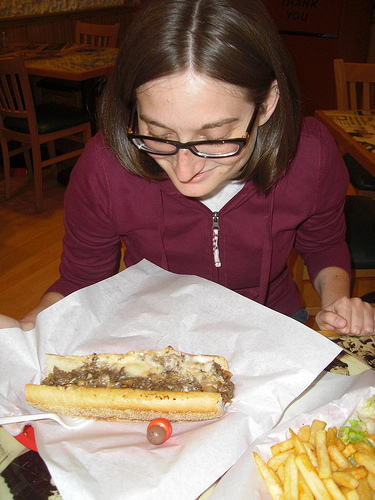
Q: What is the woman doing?
A: Looking at the food.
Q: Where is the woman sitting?
A: At a table.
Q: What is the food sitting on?
A: White paper.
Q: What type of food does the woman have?
A: A sandwich.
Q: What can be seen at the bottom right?
A: French fries.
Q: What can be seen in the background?
A: Table and chairs.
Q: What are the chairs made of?
A: Wood.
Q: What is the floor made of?
A: Hardwood.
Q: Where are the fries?
A: On the paper.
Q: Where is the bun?
A: On the paper.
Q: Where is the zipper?
A: On the jacket.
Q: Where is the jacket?
A: On the man.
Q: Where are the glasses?
A: On the man.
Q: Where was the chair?
A: On the floor.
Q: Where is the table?
A: On the floor.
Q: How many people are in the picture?
A: One.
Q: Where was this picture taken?
A: In a restaurant.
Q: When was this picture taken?
A: At mealtime.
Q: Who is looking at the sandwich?
A: A woman.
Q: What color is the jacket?
A: Purple.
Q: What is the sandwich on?
A: A piece of paper.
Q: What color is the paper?
A: White.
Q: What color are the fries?
A: Yellow.